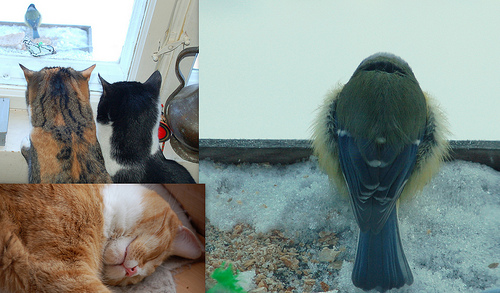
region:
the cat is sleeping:
[71, 200, 106, 275]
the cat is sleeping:
[98, 260, 172, 288]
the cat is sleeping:
[98, 225, 133, 252]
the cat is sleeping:
[88, 226, 148, 281]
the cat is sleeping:
[53, 244, 128, 286]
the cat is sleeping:
[61, 201, 144, 261]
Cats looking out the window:
[2, 45, 168, 211]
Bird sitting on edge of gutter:
[312, 60, 427, 289]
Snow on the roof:
[225, 167, 340, 282]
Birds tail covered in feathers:
[338, 185, 423, 277]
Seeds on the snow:
[243, 217, 308, 289]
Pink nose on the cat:
[114, 256, 139, 278]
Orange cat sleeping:
[8, 185, 203, 290]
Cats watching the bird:
[15, 60, 224, 172]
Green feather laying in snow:
[210, 257, 234, 292]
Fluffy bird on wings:
[313, 83, 358, 175]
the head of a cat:
[15, 54, 105, 132]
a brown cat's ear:
[77, 59, 102, 79]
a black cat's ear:
[141, 66, 166, 97]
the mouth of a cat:
[102, 227, 145, 269]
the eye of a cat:
[141, 245, 167, 265]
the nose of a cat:
[121, 262, 143, 278]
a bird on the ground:
[292, 33, 460, 291]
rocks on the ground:
[203, 216, 340, 291]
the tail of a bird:
[346, 186, 422, 291]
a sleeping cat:
[0, 184, 203, 291]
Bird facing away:
[303, 38, 440, 284]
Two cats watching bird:
[11, 55, 183, 180]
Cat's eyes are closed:
[80, 210, 192, 278]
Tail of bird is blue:
[332, 185, 424, 286]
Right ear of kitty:
[172, 220, 202, 264]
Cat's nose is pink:
[125, 260, 137, 276]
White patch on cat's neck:
[97, 195, 152, 241]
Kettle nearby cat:
[166, 42, 198, 164]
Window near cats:
[3, 5, 149, 95]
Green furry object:
[212, 252, 239, 291]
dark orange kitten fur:
[31, 194, 87, 250]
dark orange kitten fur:
[18, 201, 67, 276]